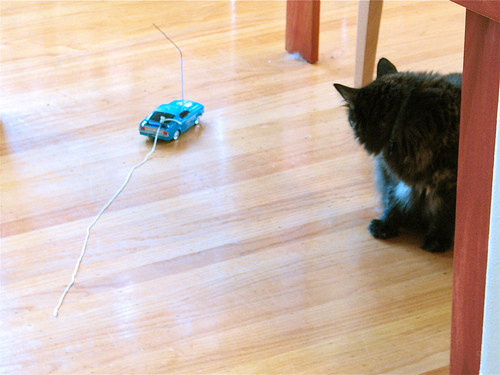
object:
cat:
[329, 54, 462, 255]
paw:
[365, 216, 403, 241]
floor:
[0, 0, 465, 375]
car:
[138, 99, 205, 142]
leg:
[282, 0, 322, 64]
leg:
[350, 0, 386, 90]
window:
[149, 111, 176, 124]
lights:
[141, 120, 149, 127]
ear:
[331, 82, 365, 115]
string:
[50, 126, 165, 315]